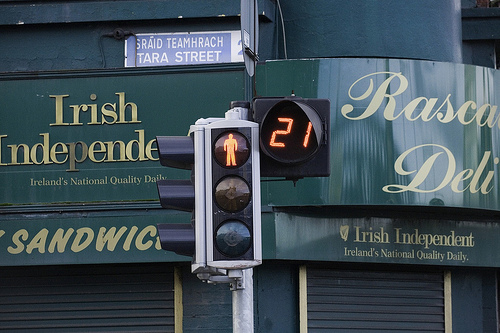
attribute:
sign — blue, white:
[124, 30, 245, 67]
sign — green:
[2, 209, 194, 267]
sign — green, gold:
[257, 58, 500, 210]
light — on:
[213, 132, 249, 168]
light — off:
[215, 178, 252, 214]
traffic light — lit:
[156, 101, 264, 291]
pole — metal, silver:
[227, 98, 254, 331]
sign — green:
[0, 64, 248, 208]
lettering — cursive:
[341, 70, 499, 197]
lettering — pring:
[29, 175, 168, 188]